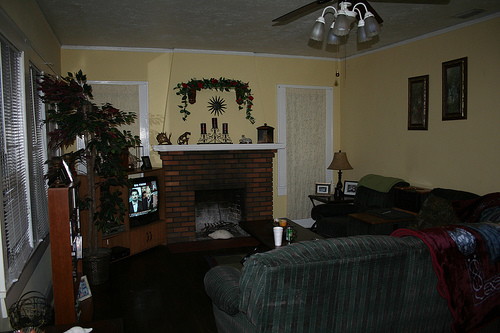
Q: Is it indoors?
A: Yes, it is indoors.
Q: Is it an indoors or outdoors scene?
A: It is indoors.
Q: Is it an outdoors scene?
A: No, it is indoors.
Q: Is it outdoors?
A: No, it is indoors.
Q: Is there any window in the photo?
A: Yes, there is a window.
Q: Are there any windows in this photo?
A: Yes, there is a window.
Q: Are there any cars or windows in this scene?
A: Yes, there is a window.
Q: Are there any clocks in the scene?
A: No, there are no clocks.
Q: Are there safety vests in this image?
A: No, there are no safety vests.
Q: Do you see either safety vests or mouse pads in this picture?
A: No, there are no safety vests or mouse pads.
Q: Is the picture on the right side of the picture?
A: Yes, the picture is on the right of the image.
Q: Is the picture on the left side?
A: No, the picture is on the right of the image.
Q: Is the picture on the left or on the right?
A: The picture is on the right of the image.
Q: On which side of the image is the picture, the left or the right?
A: The picture is on the right of the image.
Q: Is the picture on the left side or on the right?
A: The picture is on the right of the image.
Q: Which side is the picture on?
A: The picture is on the right of the image.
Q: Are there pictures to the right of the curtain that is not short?
A: Yes, there is a picture to the right of the curtain.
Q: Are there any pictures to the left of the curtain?
A: No, the picture is to the right of the curtain.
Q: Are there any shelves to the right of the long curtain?
A: No, there is a picture to the right of the curtain.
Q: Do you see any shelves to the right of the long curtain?
A: No, there is a picture to the right of the curtain.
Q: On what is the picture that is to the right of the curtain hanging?
A: The picture is hanging on the wall.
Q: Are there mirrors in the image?
A: No, there are no mirrors.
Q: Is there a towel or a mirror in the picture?
A: No, there are no mirrors or towels.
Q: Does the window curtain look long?
A: Yes, the curtain is long.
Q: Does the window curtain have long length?
A: Yes, the curtain is long.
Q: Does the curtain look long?
A: Yes, the curtain is long.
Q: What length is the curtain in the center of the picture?
A: The curtain is long.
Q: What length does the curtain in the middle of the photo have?
A: The curtain has long length.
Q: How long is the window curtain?
A: The curtain is long.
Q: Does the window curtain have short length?
A: No, the curtain is long.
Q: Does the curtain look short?
A: No, the curtain is long.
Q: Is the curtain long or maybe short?
A: The curtain is long.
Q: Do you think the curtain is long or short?
A: The curtain is long.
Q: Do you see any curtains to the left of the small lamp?
A: Yes, there is a curtain to the left of the lamp.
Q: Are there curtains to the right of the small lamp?
A: No, the curtain is to the left of the lamp.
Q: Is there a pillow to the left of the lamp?
A: No, there is a curtain to the left of the lamp.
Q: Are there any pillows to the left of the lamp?
A: No, there is a curtain to the left of the lamp.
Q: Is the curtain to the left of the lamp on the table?
A: Yes, the curtain is to the left of the lamp.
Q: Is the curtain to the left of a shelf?
A: No, the curtain is to the left of the lamp.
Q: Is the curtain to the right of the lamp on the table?
A: No, the curtain is to the left of the lamp.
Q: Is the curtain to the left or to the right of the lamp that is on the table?
A: The curtain is to the left of the lamp.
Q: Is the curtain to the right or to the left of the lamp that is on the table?
A: The curtain is to the left of the lamp.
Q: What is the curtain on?
A: The curtain is on the window.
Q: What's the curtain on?
A: The curtain is on the window.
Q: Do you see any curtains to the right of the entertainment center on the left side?
A: Yes, there is a curtain to the right of the entertainment center.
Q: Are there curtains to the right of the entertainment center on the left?
A: Yes, there is a curtain to the right of the entertainment center.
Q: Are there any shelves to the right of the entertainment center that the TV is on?
A: No, there is a curtain to the right of the entertainment center.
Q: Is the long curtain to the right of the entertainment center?
A: Yes, the curtain is to the right of the entertainment center.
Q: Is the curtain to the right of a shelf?
A: No, the curtain is to the right of the entertainment center.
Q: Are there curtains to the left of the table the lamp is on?
A: Yes, there is a curtain to the left of the table.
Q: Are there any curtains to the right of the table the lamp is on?
A: No, the curtain is to the left of the table.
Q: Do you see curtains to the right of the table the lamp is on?
A: No, the curtain is to the left of the table.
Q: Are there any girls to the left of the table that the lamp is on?
A: No, there is a curtain to the left of the table.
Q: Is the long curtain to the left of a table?
A: Yes, the curtain is to the left of a table.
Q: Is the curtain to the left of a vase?
A: No, the curtain is to the left of a table.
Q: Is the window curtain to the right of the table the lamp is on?
A: No, the curtain is to the left of the table.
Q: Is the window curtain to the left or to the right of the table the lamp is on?
A: The curtain is to the left of the table.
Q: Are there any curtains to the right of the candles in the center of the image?
A: Yes, there is a curtain to the right of the candles.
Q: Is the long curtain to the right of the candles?
A: Yes, the curtain is to the right of the candles.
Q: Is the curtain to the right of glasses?
A: No, the curtain is to the right of the candles.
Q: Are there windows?
A: Yes, there is a window.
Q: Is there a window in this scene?
A: Yes, there is a window.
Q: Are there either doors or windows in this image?
A: Yes, there is a window.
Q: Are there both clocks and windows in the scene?
A: No, there is a window but no clocks.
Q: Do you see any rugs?
A: No, there are no rugs.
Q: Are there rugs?
A: No, there are no rugs.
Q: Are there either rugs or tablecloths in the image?
A: No, there are no rugs or tablecloths.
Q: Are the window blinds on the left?
A: Yes, the blinds are on the left of the image.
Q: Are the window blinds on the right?
A: No, the blinds are on the left of the image.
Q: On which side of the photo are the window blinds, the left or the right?
A: The blinds are on the left of the image.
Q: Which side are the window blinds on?
A: The blinds are on the left of the image.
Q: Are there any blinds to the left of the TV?
A: Yes, there are blinds to the left of the TV.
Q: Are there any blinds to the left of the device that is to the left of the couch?
A: Yes, there are blinds to the left of the TV.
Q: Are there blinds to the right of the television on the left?
A: No, the blinds are to the left of the television.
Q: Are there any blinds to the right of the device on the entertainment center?
A: No, the blinds are to the left of the television.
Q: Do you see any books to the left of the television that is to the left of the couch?
A: No, there are blinds to the left of the TV.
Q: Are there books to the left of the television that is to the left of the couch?
A: No, there are blinds to the left of the TV.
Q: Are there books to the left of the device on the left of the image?
A: No, there are blinds to the left of the TV.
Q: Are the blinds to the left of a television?
A: Yes, the blinds are to the left of a television.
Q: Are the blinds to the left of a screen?
A: No, the blinds are to the left of a television.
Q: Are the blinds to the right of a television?
A: No, the blinds are to the left of a television.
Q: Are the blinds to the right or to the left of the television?
A: The blinds are to the left of the television.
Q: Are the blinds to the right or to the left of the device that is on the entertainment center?
A: The blinds are to the left of the television.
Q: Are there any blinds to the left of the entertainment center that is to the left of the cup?
A: Yes, there are blinds to the left of the entertainment center.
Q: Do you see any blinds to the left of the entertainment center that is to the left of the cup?
A: Yes, there are blinds to the left of the entertainment center.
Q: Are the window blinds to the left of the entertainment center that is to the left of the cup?
A: Yes, the blinds are to the left of the entertainment center.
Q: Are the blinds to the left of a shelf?
A: No, the blinds are to the left of the entertainment center.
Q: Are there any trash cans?
A: No, there are no trash cans.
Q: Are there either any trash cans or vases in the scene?
A: No, there are no trash cans or vases.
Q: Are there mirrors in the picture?
A: No, there are no mirrors.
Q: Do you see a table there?
A: Yes, there is a table.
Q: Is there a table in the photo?
A: Yes, there is a table.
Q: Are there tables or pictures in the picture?
A: Yes, there is a table.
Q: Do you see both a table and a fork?
A: No, there is a table but no forks.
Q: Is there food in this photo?
A: No, there is no food.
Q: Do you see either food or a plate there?
A: No, there are no food or plates.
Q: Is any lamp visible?
A: Yes, there is a lamp.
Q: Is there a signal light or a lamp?
A: Yes, there is a lamp.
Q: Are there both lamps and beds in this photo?
A: No, there is a lamp but no beds.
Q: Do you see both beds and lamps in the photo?
A: No, there is a lamp but no beds.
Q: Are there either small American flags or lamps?
A: Yes, there is a small lamp.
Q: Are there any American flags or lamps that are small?
A: Yes, the lamp is small.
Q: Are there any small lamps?
A: Yes, there is a small lamp.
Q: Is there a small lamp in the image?
A: Yes, there is a small lamp.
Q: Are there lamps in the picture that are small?
A: Yes, there is a lamp that is small.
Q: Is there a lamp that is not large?
A: Yes, there is a small lamp.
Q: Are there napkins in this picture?
A: No, there are no napkins.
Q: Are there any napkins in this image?
A: No, there are no napkins.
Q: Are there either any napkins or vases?
A: No, there are no napkins or vases.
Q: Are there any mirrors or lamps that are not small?
A: No, there is a lamp but it is small.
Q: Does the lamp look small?
A: Yes, the lamp is small.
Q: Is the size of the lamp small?
A: Yes, the lamp is small.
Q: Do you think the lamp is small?
A: Yes, the lamp is small.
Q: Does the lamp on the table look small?
A: Yes, the lamp is small.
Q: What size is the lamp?
A: The lamp is small.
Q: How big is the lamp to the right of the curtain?
A: The lamp is small.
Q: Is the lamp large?
A: No, the lamp is small.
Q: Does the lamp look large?
A: No, the lamp is small.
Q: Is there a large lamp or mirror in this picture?
A: No, there is a lamp but it is small.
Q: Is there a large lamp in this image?
A: No, there is a lamp but it is small.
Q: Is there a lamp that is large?
A: No, there is a lamp but it is small.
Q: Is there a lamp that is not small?
A: No, there is a lamp but it is small.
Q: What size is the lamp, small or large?
A: The lamp is small.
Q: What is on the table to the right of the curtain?
A: The lamp is on the table.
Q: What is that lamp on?
A: The lamp is on the table.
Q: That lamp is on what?
A: The lamp is on the table.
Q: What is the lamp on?
A: The lamp is on the table.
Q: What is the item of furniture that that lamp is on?
A: The piece of furniture is a table.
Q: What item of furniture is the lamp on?
A: The lamp is on the table.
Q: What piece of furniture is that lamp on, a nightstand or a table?
A: The lamp is on a table.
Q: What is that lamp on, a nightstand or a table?
A: The lamp is on a table.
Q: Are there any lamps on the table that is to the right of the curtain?
A: Yes, there is a lamp on the table.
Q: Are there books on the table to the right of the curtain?
A: No, there is a lamp on the table.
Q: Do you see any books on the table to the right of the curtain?
A: No, there is a lamp on the table.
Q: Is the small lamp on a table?
A: Yes, the lamp is on a table.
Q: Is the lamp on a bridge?
A: No, the lamp is on a table.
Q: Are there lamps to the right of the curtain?
A: Yes, there is a lamp to the right of the curtain.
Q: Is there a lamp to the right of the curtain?
A: Yes, there is a lamp to the right of the curtain.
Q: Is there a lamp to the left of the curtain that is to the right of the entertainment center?
A: No, the lamp is to the right of the curtain.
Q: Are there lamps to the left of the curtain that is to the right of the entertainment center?
A: No, the lamp is to the right of the curtain.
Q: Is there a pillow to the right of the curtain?
A: No, there is a lamp to the right of the curtain.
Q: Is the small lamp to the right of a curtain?
A: Yes, the lamp is to the right of a curtain.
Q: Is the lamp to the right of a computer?
A: No, the lamp is to the right of a curtain.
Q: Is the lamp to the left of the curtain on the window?
A: No, the lamp is to the right of the curtain.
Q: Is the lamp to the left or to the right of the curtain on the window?
A: The lamp is to the right of the curtain.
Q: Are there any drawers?
A: No, there are no drawers.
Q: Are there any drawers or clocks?
A: No, there are no drawers or clocks.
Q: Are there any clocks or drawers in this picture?
A: No, there are no drawers or clocks.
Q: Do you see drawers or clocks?
A: No, there are no drawers or clocks.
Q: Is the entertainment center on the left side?
A: Yes, the entertainment center is on the left of the image.